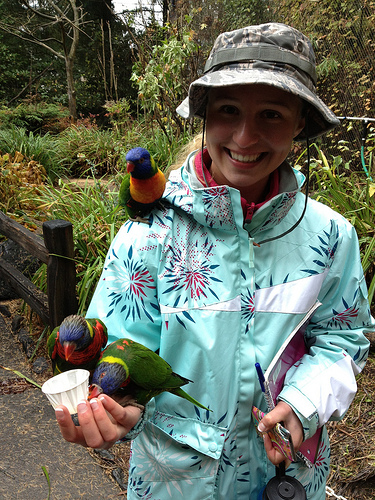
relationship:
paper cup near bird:
[42, 369, 91, 415] [46, 314, 108, 381]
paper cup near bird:
[42, 369, 91, 415] [87, 338, 214, 413]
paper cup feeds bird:
[39, 368, 93, 417] [119, 147, 166, 225]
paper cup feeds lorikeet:
[39, 368, 93, 417] [45, 311, 107, 371]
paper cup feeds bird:
[39, 368, 93, 417] [87, 338, 214, 413]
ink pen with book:
[254, 364, 270, 390] [262, 298, 322, 469]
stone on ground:
[23, 442, 81, 498] [15, 351, 69, 482]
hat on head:
[172, 17, 341, 144] [171, 15, 340, 196]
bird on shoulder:
[119, 147, 166, 225] [110, 158, 203, 282]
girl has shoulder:
[57, 24, 373, 498] [110, 158, 203, 282]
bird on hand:
[46, 314, 108, 381] [48, 380, 158, 452]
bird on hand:
[87, 338, 214, 413] [48, 380, 158, 452]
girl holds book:
[57, 24, 373, 498] [263, 298, 324, 466]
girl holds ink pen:
[57, 24, 373, 498] [254, 362, 275, 413]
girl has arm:
[57, 24, 373, 498] [261, 227, 368, 411]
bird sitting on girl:
[119, 147, 166, 225] [53, 22, 375, 500]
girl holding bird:
[53, 22, 375, 500] [103, 132, 171, 212]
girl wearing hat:
[53, 22, 375, 500] [176, 22, 341, 142]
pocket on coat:
[126, 408, 230, 498] [84, 145, 375, 499]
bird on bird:
[119, 147, 166, 225] [87, 338, 214, 413]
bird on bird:
[119, 147, 166, 225] [46, 314, 108, 381]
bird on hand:
[119, 147, 166, 225] [54, 393, 141, 450]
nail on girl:
[74, 400, 86, 413] [53, 22, 375, 500]